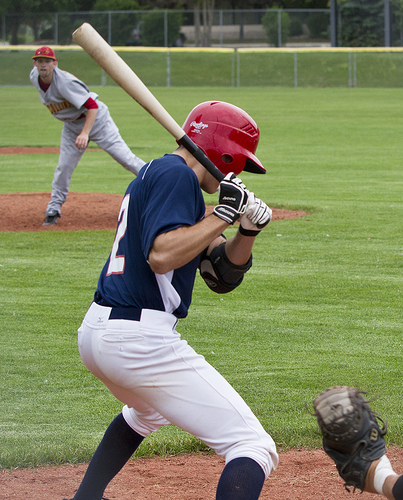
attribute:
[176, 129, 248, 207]
handle — brown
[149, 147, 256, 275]
skin — light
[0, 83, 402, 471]
grass — green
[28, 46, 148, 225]
player — baseball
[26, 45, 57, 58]
hat — red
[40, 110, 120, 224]
pants — grey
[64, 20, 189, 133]
bat — brown, black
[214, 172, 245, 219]
glove — white, black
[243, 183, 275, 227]
glove — black, white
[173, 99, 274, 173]
helmet — red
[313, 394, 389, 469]
mitt — black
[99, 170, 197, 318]
jersey — blue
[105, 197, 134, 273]
numeral — white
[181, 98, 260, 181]
helmet — red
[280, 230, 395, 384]
grass — green, healthy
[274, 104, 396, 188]
grass — green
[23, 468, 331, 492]
ground — brown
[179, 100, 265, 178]
helmet — red, hard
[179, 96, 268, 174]
helmet — red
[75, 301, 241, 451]
pants — white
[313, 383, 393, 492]
mitt — black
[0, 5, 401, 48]
fence — chain link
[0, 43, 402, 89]
fence — chain link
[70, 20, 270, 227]
bat — wooden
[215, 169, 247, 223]
glove — black, white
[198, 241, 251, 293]
elbow brace — black, white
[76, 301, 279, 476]
pants — white, uniform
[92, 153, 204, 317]
jersey — dark, blue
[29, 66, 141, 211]
uniform — gray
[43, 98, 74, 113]
detail — red, yellow